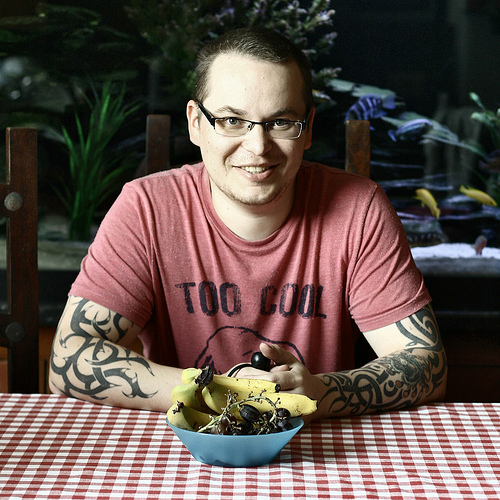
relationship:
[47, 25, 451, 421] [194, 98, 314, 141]
man wearing glasses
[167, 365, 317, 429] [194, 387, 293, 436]
bananas next to grapes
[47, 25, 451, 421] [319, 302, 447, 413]
man has tattoos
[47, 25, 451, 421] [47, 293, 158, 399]
man has tattoos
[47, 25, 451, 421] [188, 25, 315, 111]
man has hair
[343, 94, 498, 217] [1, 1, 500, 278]
fish inside of aquarium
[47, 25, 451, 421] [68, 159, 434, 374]
man wearing shirt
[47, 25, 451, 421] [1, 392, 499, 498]
man sitting at table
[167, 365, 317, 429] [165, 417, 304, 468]
bananas inside of bowl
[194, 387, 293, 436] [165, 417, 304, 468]
grapes inside of bowl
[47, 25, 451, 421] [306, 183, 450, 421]
man has arm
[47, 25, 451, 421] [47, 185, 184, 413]
man has arm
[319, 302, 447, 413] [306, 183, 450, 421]
tattoos covering arm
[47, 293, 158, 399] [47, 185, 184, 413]
tattoos covering arm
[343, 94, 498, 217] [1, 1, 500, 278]
fish swimming in aquarium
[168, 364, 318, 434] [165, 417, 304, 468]
fruit inside of bowl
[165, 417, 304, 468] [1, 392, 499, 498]
bowl on top of table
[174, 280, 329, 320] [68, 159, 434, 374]
too cool writting on front of shirt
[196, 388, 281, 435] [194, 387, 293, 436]
stem holding grapes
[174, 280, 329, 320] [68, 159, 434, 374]
too cool on front of shirt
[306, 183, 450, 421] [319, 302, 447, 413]
arm covered in tattoos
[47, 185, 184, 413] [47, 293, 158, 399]
arm covered in tattoos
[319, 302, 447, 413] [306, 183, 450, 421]
tattoos covering mans arm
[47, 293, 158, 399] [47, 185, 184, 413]
tattoos covering mans arm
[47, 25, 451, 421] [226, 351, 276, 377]
man holding object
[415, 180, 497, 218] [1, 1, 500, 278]
fish inside of aquarium